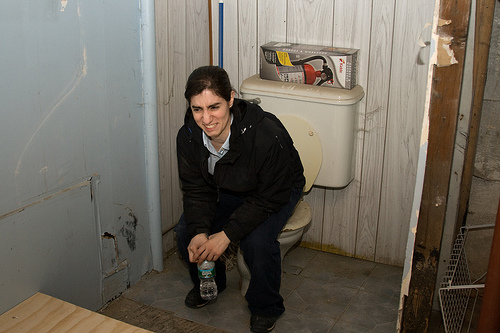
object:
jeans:
[172, 187, 302, 317]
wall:
[0, 1, 160, 313]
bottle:
[196, 259, 217, 301]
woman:
[171, 65, 306, 333]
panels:
[208, 0, 438, 270]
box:
[259, 37, 360, 91]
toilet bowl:
[236, 114, 323, 296]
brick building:
[293, 137, 406, 266]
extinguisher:
[258, 40, 359, 91]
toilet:
[236, 72, 365, 297]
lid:
[277, 114, 323, 192]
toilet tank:
[238, 73, 365, 189]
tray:
[438, 223, 494, 333]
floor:
[98, 244, 403, 327]